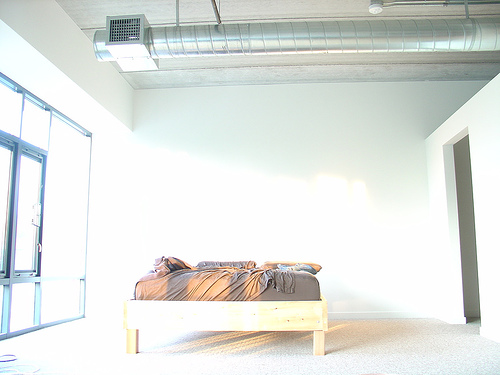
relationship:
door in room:
[451, 133, 479, 331] [0, 0, 484, 370]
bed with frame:
[120, 193, 394, 373] [91, 281, 386, 371]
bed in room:
[120, 255, 331, 358] [99, 129, 485, 368]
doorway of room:
[419, 118, 485, 298] [71, 125, 482, 338]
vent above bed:
[79, 9, 433, 99] [120, 255, 331, 358]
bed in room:
[120, 255, 331, 358] [86, 155, 474, 344]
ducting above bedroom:
[144, 19, 500, 83] [15, 11, 480, 338]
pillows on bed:
[143, 257, 358, 289] [115, 227, 412, 363]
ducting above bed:
[144, 19, 500, 83] [82, 226, 382, 361]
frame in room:
[111, 226, 384, 364] [43, 76, 484, 336]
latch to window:
[18, 206, 58, 269] [5, 103, 104, 353]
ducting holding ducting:
[144, 19, 500, 83] [144, 7, 444, 86]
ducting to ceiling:
[144, 7, 444, 86] [60, 0, 431, 127]